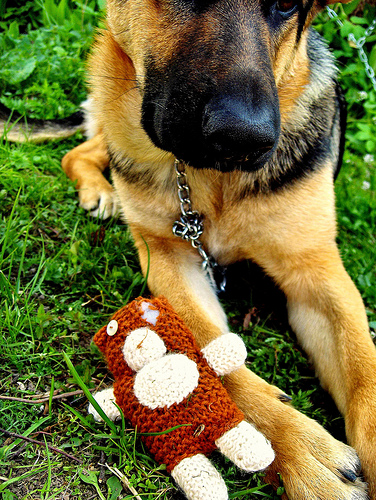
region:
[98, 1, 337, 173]
A dog face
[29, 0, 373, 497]
A brown, white and black color dog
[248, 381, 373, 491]
Legs of the dog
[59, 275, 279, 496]
Toys near the dog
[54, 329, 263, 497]
Brown and white color toys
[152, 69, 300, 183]
Black color nose and mouth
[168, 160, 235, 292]
Silver chain tied in the dog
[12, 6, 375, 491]
A dog laydown in the grass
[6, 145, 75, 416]
Green color grass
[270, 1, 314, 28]
Eyes of the dog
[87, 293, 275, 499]
A brown and white teddy bear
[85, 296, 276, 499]
A hand knitted teddy bear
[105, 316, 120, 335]
A teddy bear's right eye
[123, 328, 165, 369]
A teddy bear's nose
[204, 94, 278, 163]
A dog's black nose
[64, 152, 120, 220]
A dog's right leg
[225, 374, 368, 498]
A dog's right paw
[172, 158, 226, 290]
A shiny metal dog chain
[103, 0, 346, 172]
A dog's head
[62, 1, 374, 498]
A German Shepard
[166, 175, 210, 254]
a chain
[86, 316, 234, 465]
a stuffed animal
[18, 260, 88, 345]
the green grass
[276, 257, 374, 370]
the dogs leg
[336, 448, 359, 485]
the dogs nail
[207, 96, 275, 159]
the dogs nose is black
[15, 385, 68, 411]
a little stick in the grass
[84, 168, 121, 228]
the dogs paw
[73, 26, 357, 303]
the dog is laying on the grass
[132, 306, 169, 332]
cotton in the stuffed animal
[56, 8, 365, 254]
dog reclined in grass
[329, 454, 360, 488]
black toenail on dog paw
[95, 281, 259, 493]
knit doll on ground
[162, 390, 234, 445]
brown yarn on toy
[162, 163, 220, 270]
chain on dog chest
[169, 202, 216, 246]
knot in metal chain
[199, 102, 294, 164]
black nose on dog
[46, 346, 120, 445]
blade of green grass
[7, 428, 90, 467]
wood twig on ground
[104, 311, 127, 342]
button on doll face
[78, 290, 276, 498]
orange and white stuffed dog toy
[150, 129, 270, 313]
dog chain attached to dog collar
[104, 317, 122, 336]
button used for eye of dog toy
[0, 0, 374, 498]
brown and black german shepherd dog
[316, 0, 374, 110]
piece of chain connected to dog's chain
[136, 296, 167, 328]
white stuffing inside dog toy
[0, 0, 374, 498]
grassy yard with dog sitting in it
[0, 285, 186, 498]
small wooden sticks lying in yard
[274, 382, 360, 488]
black trimmed hard dog claws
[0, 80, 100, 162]
dog tail lying on the grassy yard